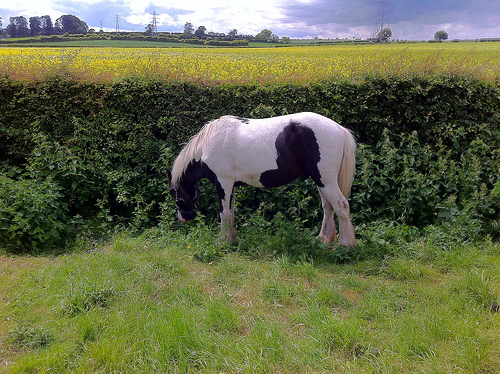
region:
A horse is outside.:
[151, 95, 376, 287]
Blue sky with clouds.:
[102, 2, 344, 24]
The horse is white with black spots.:
[146, 100, 381, 271]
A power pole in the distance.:
[103, 8, 124, 38]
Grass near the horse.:
[60, 260, 490, 371]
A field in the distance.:
[16, 42, 496, 72]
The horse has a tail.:
[337, 125, 358, 193]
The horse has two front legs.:
[196, 173, 259, 268]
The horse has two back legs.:
[303, 163, 366, 255]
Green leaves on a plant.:
[12, 94, 126, 234]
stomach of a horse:
[246, 142, 276, 169]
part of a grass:
[329, 287, 384, 336]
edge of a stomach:
[236, 108, 279, 198]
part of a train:
[198, 305, 242, 349]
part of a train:
[343, 157, 363, 202]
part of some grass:
[258, 270, 305, 322]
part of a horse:
[155, 166, 216, 225]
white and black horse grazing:
[183, 104, 370, 236]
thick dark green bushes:
[38, 82, 487, 264]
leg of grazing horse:
[212, 187, 232, 266]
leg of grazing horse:
[229, 174, 239, 247]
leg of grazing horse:
[319, 157, 373, 249]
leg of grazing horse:
[308, 189, 338, 246]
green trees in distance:
[9, 10, 486, 32]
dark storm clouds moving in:
[299, 3, 499, 52]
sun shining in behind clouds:
[10, 2, 273, 37]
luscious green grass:
[11, 256, 496, 354]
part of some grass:
[180, 252, 216, 289]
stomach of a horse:
[248, 155, 283, 192]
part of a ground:
[251, 309, 298, 354]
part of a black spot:
[296, 147, 317, 178]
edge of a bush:
[113, 63, 155, 99]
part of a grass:
[174, 250, 234, 315]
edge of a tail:
[348, 165, 359, 202]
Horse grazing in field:
[124, 67, 413, 289]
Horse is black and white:
[139, 92, 394, 260]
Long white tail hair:
[335, 126, 364, 202]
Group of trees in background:
[14, 12, 91, 35]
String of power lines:
[95, 13, 164, 33]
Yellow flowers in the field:
[105, 24, 360, 94]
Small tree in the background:
[428, 26, 452, 43]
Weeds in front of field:
[8, 73, 117, 251]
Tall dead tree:
[370, 4, 397, 43]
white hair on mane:
[151, 117, 239, 175]